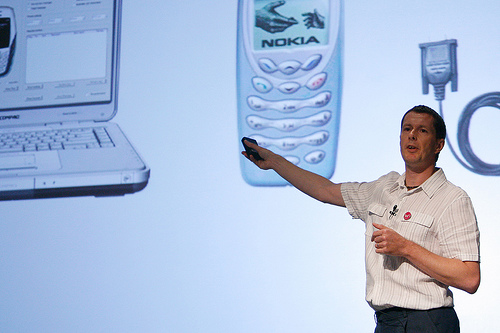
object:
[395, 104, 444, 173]
head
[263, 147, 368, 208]
arm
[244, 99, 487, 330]
man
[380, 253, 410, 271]
shadow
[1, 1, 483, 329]
background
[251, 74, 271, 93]
button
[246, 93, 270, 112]
button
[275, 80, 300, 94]
button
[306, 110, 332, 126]
button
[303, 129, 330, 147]
button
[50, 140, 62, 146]
key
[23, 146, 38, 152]
key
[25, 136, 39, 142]
key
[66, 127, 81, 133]
key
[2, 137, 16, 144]
key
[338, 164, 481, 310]
shirt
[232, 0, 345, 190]
cell phone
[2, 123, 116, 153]
keyboard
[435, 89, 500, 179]
cable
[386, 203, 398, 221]
microphone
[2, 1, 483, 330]
image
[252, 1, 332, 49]
screen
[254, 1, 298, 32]
hand image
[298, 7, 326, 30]
hand image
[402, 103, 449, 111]
hair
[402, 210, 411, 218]
button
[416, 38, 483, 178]
computer cable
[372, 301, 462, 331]
dress pants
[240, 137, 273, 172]
hand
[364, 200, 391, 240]
shirt pocket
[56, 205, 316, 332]
wall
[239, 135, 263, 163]
phone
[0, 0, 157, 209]
graphic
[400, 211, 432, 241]
pocket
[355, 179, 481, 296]
forearm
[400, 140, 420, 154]
mouth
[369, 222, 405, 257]
hand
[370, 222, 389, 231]
thumb